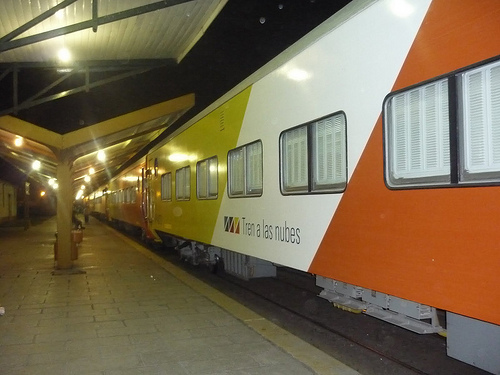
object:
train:
[82, 0, 499, 374]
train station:
[1, 0, 500, 374]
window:
[277, 124, 312, 196]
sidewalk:
[1, 210, 358, 374]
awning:
[1, 1, 230, 66]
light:
[52, 47, 75, 67]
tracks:
[91, 218, 497, 375]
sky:
[3, 1, 353, 172]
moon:
[255, 15, 269, 29]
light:
[96, 149, 110, 165]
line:
[91, 210, 363, 374]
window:
[244, 138, 265, 198]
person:
[73, 210, 86, 229]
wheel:
[209, 250, 226, 276]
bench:
[53, 241, 80, 259]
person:
[81, 203, 94, 225]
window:
[382, 75, 455, 187]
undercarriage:
[173, 236, 500, 375]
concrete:
[126, 230, 499, 374]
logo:
[223, 216, 299, 246]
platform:
[0, 214, 363, 375]